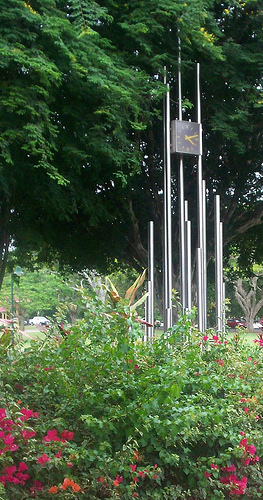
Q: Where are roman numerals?
A: On clock.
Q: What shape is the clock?
A: Square.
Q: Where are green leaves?
A: On trees.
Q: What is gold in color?
A: Clock's hands.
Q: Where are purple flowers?
A: In bushes.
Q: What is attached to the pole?
A: Clock.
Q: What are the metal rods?
A: Poles.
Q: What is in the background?
A: Trees.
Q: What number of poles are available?
A: 5.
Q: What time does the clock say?
A: 4:17.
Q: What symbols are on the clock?
A: Roman numeral.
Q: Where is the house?
A: On the back left.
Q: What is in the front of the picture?
A: Bushes.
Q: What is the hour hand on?
A: 4.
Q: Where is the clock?
A: On metal tubes.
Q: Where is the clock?
A: Near the top of the poles.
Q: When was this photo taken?
A: During the daytime.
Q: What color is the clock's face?
A: Black.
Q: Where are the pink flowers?
A: In the bottom of the photo.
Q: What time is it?
A: 4:12.